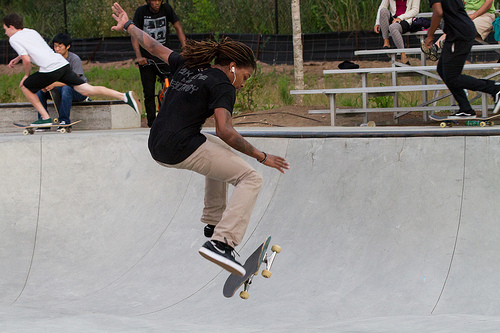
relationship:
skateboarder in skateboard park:
[102, 1, 297, 282] [7, 121, 494, 333]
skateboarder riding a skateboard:
[102, 1, 297, 282] [216, 235, 287, 311]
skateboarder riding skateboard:
[417, 0, 500, 113] [426, 107, 498, 128]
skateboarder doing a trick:
[102, 1, 297, 282] [99, 1, 312, 310]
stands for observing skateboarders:
[289, 5, 495, 121] [102, 1, 297, 282]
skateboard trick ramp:
[216, 235, 287, 311] [7, 121, 494, 333]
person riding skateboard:
[2, 9, 141, 126] [11, 118, 84, 135]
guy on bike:
[127, 0, 188, 60] [144, 56, 168, 105]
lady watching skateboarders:
[370, 0, 423, 71] [1, 1, 469, 300]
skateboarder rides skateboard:
[102, 1, 297, 282] [216, 235, 287, 311]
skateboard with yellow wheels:
[216, 235, 287, 311] [236, 241, 284, 302]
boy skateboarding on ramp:
[102, 1, 297, 282] [7, 121, 494, 333]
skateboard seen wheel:
[216, 235, 287, 311] [259, 263, 275, 280]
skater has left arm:
[102, 1, 297, 282] [105, 2, 189, 73]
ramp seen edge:
[7, 121, 494, 333] [0, 123, 500, 140]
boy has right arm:
[102, 1, 297, 282] [211, 84, 293, 180]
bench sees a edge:
[289, 5, 495, 121] [280, 40, 363, 123]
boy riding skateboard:
[102, 1, 297, 282] [216, 235, 287, 311]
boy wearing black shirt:
[102, 1, 297, 282] [145, 49, 239, 166]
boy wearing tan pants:
[102, 1, 297, 282] [169, 126, 266, 256]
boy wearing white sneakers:
[102, 1, 297, 282] [193, 219, 249, 279]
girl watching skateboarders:
[370, 1, 423, 71] [1, 1, 469, 300]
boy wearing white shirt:
[2, 9, 141, 126] [8, 27, 70, 77]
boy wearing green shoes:
[2, 9, 141, 126] [31, 88, 143, 122]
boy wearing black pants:
[417, 0, 500, 113] [431, 35, 498, 117]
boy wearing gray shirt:
[417, 0, 500, 113] [433, 0, 483, 47]